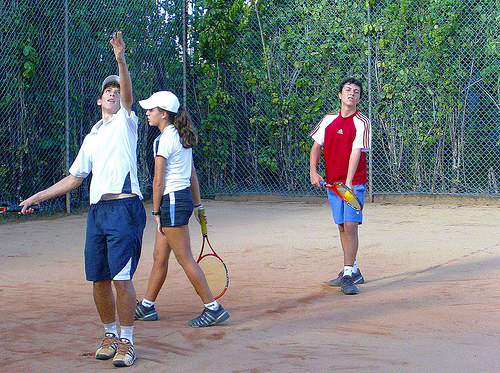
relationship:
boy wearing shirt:
[306, 78, 370, 297] [307, 111, 371, 186]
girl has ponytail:
[133, 90, 229, 327] [173, 107, 197, 147]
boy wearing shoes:
[19, 29, 149, 370] [94, 329, 136, 369]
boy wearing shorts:
[19, 29, 149, 370] [76, 195, 148, 285]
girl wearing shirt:
[133, 90, 229, 327] [146, 127, 210, 204]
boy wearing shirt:
[19, 29, 149, 370] [68, 99, 143, 201]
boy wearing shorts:
[306, 78, 370, 297] [308, 158, 393, 233]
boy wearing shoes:
[306, 76, 378, 208] [327, 264, 369, 299]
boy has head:
[306, 78, 370, 297] [332, 79, 364, 122]